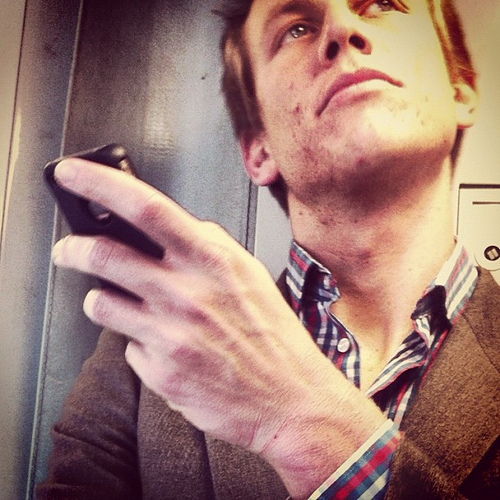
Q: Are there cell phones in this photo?
A: Yes, there is a cell phone.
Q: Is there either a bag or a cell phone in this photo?
A: Yes, there is a cell phone.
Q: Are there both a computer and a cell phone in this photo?
A: No, there is a cell phone but no computers.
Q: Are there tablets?
A: No, there are no tablets.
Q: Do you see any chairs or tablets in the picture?
A: No, there are no tablets or chairs.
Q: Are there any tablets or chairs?
A: No, there are no tablets or chairs.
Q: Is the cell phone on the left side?
A: Yes, the cell phone is on the left of the image.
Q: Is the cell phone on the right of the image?
A: No, the cell phone is on the left of the image.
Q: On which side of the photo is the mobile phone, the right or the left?
A: The mobile phone is on the left of the image.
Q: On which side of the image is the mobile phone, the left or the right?
A: The mobile phone is on the left of the image.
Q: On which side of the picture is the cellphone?
A: The cellphone is on the left of the image.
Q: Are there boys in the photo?
A: No, there are no boys.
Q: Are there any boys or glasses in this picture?
A: No, there are no boys or glasses.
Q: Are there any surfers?
A: No, there are no surfers.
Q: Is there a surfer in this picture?
A: No, there are no surfers.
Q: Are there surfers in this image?
A: No, there are no surfers.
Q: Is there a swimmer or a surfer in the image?
A: No, there are no surfers or swimmers.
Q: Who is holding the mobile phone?
A: The man is holding the mobile phone.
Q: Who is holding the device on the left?
A: The man is holding the mobile phone.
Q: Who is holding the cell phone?
A: The man is holding the mobile phone.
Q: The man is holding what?
A: The man is holding the mobile phone.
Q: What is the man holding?
A: The man is holding the mobile phone.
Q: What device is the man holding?
A: The man is holding the cell phone.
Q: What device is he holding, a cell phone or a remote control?
A: The man is holding a cell phone.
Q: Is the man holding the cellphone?
A: Yes, the man is holding the cellphone.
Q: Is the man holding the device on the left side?
A: Yes, the man is holding the cellphone.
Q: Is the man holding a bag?
A: No, the man is holding the cellphone.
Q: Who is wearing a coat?
A: The man is wearing a coat.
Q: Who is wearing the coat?
A: The man is wearing a coat.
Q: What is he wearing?
A: The man is wearing a coat.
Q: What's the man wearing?
A: The man is wearing a coat.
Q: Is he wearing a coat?
A: Yes, the man is wearing a coat.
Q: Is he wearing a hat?
A: No, the man is wearing a coat.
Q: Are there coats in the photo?
A: Yes, there is a coat.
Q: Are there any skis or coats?
A: Yes, there is a coat.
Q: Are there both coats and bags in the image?
A: No, there is a coat but no bags.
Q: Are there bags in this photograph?
A: No, there are no bags.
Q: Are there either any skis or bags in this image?
A: No, there are no bags or skis.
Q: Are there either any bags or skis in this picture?
A: No, there are no bags or skis.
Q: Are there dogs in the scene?
A: No, there are no dogs.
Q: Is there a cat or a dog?
A: No, there are no dogs or cats.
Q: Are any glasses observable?
A: No, there are no glasses.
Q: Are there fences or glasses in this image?
A: No, there are no glasses or fences.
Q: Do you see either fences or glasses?
A: No, there are no glasses or fences.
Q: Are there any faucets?
A: No, there are no faucets.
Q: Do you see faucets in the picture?
A: No, there are no faucets.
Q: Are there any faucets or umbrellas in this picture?
A: No, there are no faucets or umbrellas.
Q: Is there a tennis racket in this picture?
A: No, there are no rackets.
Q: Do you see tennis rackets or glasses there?
A: No, there are no tennis rackets or glasses.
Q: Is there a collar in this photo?
A: Yes, there is a collar.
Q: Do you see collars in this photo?
A: Yes, there is a collar.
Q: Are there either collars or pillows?
A: Yes, there is a collar.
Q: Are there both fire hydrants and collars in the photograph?
A: No, there is a collar but no fire hydrants.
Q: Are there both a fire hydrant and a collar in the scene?
A: No, there is a collar but no fire hydrants.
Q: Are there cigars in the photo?
A: No, there are no cigars.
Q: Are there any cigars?
A: No, there are no cigars.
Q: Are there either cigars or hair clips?
A: No, there are no cigars or hair clips.